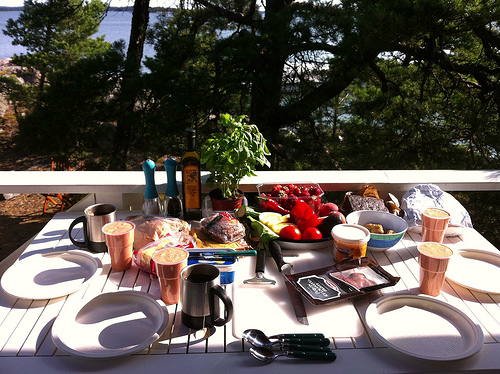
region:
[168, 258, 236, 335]
a silver metal cup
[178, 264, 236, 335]
a silver metal cup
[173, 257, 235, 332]
a silver metal cup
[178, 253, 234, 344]
a silver metal cup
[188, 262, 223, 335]
a silver metal cup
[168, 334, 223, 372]
a white wooden table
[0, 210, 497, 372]
White table with slats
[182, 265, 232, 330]
Stainless steel mug with black handle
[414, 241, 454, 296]
Full glass of beverage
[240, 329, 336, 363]
Metal spoons with plastic handles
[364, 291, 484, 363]
White empty plate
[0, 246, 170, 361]
2 white empty plates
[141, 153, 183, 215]
Salt and pepper shakers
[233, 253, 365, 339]
White cutting board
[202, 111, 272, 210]
Potted plant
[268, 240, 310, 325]
Serrated knife with black handle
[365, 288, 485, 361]
a white paper plate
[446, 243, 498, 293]
a white paper plate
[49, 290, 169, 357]
a white paper plate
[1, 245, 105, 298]
a white paper plate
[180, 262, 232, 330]
a metal coffee mug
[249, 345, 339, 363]
a black handled spoon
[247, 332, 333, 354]
a black handled spoon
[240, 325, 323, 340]
a black handled spoon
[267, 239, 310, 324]
a black handled knife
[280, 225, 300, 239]
a bright red tomato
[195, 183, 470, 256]
Food is on the table.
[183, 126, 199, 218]
Steak sauce is on the table.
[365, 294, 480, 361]
Plates are on the table.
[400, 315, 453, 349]
The plate is white.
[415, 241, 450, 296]
Cups are on the table.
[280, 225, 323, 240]
Tomatoes are on the table.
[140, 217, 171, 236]
Bread is on the table.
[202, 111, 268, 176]
A plant is on the table.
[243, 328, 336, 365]
Spoons are on the table.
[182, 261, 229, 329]
A mug is on the table.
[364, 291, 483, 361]
Plate on a table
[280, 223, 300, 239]
Tomato on a plate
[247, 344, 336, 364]
A spoon with a handle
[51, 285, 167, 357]
white plastic plate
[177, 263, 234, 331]
A mug on a table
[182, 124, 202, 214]
Bottle on a table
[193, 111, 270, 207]
Green plant on a table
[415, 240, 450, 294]
A drink in a cup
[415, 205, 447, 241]
Drink in a light colored cup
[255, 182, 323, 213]
Container full of organic food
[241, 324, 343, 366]
Spoons on a table.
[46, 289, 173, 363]
Paper plate on a table.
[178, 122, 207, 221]
Bottle of vinegar.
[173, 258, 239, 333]
Silver and black coffee mug.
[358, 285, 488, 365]
white plate on picnic table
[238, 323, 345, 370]
group of large spoons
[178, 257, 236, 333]
coffee mug on table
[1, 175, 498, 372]
picnic table constructed of white boards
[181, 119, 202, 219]
tall bottle of balsamic vinegar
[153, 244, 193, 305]
creamy drink in colorful cup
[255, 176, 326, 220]
clear bowl of fresh berries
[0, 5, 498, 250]
green trees behind porch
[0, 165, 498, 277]
white porch railing for porch frame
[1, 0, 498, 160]
blue body of water